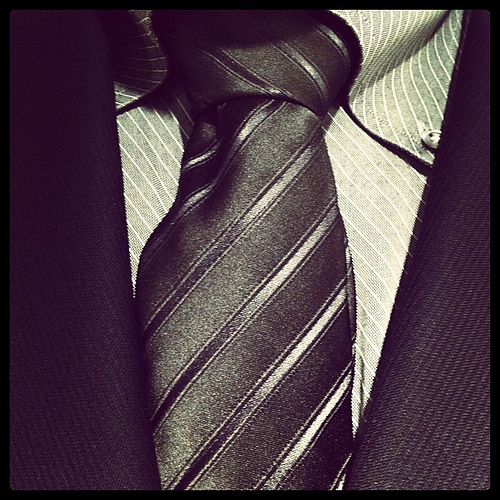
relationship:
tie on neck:
[193, 108, 307, 326] [138, 9, 390, 81]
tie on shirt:
[193, 108, 307, 326] [133, 119, 181, 203]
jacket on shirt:
[429, 183, 499, 447] [133, 119, 181, 203]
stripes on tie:
[349, 148, 400, 257] [193, 108, 307, 326]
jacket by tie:
[429, 183, 499, 447] [193, 108, 307, 326]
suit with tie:
[40, 59, 201, 479] [193, 108, 307, 326]